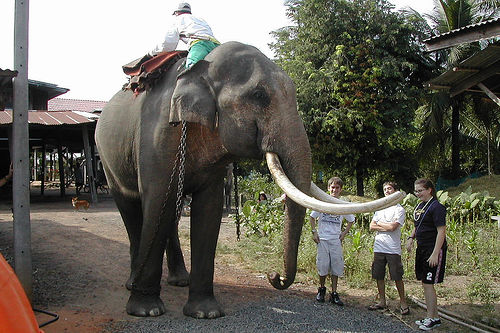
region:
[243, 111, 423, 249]
two long white tusks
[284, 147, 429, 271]
two long white tusks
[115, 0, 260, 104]
a man riding an elephant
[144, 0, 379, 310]
a man riding an elephant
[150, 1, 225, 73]
person is wearing green pants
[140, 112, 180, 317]
chain attached from ear to legs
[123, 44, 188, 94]
blanket on top of elephants back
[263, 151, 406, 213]
long tusks of elephant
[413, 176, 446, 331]
girl smiling at elephant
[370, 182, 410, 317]
boy wearing flip flops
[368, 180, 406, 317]
this person has arms tucked in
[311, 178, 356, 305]
holds arms by side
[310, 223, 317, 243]
wearing a watch on right hand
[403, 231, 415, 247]
girl wearing watch on right hand also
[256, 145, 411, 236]
long ivory tusks on the elephant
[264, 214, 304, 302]
long elephant trunk hanging in a J shape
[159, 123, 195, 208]
silver chains on the elephant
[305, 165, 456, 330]
three kids looking at the elephant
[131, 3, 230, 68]
person on top of the elephant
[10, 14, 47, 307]
post beside the elephant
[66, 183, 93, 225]
dog behind the elephant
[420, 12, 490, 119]
roof of the building behind the kids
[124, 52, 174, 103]
blankets on top of the elephant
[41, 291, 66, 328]
black cord on the ground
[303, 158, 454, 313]
three kids watching the elephant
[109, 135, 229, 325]
the elephant is wearing a chain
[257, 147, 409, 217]
the tusks of an elephant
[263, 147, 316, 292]
the trunk of an elephant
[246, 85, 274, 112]
an eye of an elaphant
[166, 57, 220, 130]
the ear of an elephant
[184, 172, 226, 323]
the front leg of an elephant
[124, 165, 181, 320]
the front leg of an elephant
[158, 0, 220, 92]
a man sitting on top of an elephant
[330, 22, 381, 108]
the leaves of a tree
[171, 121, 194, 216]
a chain on the neck of an elephant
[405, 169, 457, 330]
a girl standing by an elephant